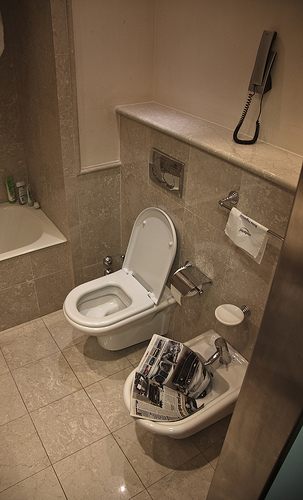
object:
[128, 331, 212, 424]
magazine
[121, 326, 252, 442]
bowl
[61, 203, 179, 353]
toilet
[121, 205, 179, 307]
lid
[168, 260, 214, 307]
roll of toilet paper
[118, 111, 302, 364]
wall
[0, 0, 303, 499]
bathroom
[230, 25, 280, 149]
phone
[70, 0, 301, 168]
wall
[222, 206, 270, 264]
bag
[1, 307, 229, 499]
floor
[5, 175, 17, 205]
bottle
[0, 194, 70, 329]
bathtub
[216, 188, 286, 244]
towel rack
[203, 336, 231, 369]
faucet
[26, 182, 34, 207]
bottle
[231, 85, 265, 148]
cord